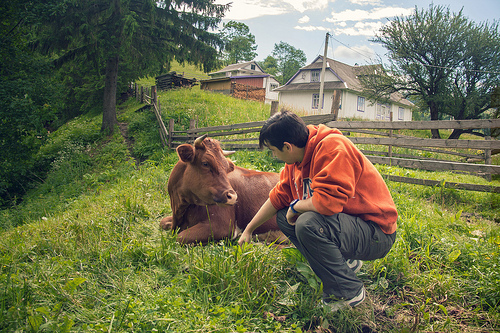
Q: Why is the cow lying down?
A: It is resting.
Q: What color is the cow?
A: Brown.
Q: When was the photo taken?
A: Daytime.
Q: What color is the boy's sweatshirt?
A: Orange.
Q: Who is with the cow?
A: The boy.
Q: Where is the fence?
A: Behind the boy.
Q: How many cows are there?
A: One.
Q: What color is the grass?
A: Green.